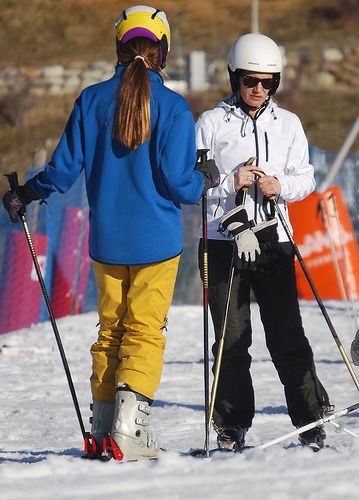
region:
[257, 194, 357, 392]
a long black and yellow pole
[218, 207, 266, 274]
a gray and black glove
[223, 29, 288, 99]
a white helmet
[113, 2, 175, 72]
a yellow and white helmet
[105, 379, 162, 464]
a woman's snow show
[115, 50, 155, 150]
a girl's long ponytail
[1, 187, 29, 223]
a black glove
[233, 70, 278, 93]
a woman's black sunglasses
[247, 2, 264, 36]
part of a gray pole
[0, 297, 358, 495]
white snow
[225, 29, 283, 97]
white skier's ski helmet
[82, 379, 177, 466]
pair of ski boots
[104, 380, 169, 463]
right ski boot of woman on left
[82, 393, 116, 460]
left ski boot of woman on left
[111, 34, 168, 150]
ponytail of woman on left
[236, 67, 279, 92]
black sunglasses of woman on right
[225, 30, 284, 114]
concerned expression of woman on right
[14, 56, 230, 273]
blue fleece ski jacket with black trim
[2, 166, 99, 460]
left ski pole of woman on left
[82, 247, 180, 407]
yellow ski pants of woman on left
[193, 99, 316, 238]
black and white sweater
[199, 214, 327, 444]
black pants on man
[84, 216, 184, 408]
yellow pants of girl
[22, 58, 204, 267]
dark blue sweater of girl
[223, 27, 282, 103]
white helmet on man head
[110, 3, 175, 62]
purple yellow and white helmet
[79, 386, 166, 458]
metallic gray boots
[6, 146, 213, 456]
two black and red poles of girl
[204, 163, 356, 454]
two black and yellow poles of man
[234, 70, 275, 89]
black glasses of man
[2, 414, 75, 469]
shadows in the snow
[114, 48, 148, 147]
a woman's pony tail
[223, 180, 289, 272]
gloves hanging from skis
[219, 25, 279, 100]
woman with helmet and sunglasses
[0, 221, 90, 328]
protective barrier on a course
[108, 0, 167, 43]
a purple, gold, and white helmet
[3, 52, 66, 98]
out of focus buildings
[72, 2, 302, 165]
two skiers facing opposite directions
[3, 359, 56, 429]
well-trod snow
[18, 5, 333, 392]
women at a ski slope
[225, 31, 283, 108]
white helmet on a woman's head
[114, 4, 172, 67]
white yellow and purple helmet on a woman's head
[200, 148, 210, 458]
black ski pole in a woman's hand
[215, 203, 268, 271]
gray and black golves in a woman's hand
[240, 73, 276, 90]
dark shades over a woman's eyes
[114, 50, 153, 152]
ponytail held by white ponytail holder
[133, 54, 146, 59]
white ponytail holder on a woman's hair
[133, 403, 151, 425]
gray buckles on the woman's footwear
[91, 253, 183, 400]
yellow pants on a woman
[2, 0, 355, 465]
two female skiers